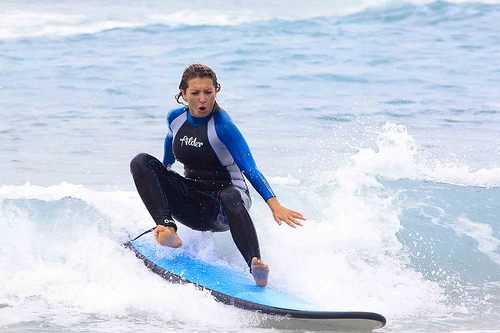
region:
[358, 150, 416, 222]
part of a splash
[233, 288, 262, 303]
par tof a board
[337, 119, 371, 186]
part of a splash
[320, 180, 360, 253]
part of a splash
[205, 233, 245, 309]
part of a board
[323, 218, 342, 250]
part of a splash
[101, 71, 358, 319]
female surfer on blue board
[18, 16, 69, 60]
white and blue ocean waves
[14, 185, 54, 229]
white and blue ocean waves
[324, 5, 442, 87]
white and blue ocean waves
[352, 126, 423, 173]
white and blue ocean waves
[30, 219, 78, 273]
white and blue ocean waves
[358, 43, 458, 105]
white and blue ocean waves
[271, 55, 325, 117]
white and blue ocean waves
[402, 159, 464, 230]
white and blue ocean waves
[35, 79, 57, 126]
white and blue ocean waves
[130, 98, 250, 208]
wearing a wetsuit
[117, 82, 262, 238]
the surfer has a wetsuit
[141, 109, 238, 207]
the wetsuit is black and blue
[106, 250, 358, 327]
she is surfing in the ocean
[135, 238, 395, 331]
the surfboard is blue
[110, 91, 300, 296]
she is falling back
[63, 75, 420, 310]
surfing in the water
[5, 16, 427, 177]
the ocean is clear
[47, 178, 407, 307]
waves producing white foam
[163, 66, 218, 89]
her hair is brown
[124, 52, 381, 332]
a women surfing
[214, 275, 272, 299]
a surfboard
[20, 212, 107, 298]
the water is white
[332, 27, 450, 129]
the water is blue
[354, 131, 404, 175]
a splahs of water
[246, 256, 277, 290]
the womens foot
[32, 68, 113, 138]
the water is blue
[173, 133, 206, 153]
writing on the shirt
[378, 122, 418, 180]
the water is white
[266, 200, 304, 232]
a womens hand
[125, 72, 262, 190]
this is a woman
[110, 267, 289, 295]
this is a board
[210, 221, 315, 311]
this is a blue board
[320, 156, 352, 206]
this is a beach wave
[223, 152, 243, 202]
this is a wetsuit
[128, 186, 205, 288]
this is a foot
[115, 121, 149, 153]
this is a knee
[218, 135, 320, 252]
this is an arm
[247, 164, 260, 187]
this is an elbow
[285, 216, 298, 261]
these are some fingers